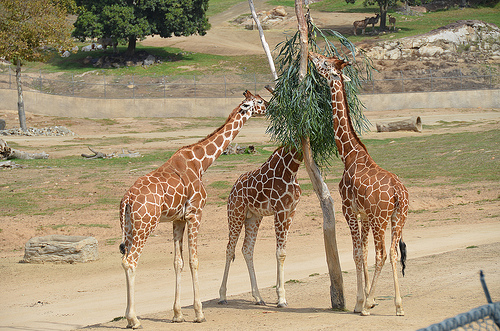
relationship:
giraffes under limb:
[116, 89, 276, 324] [264, 5, 373, 176]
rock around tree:
[8, 123, 74, 140] [1, 2, 80, 134]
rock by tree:
[8, 123, 74, 140] [1, 2, 80, 134]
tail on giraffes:
[119, 201, 129, 254] [116, 89, 276, 324]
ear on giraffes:
[332, 56, 342, 70] [308, 51, 411, 315]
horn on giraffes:
[242, 89, 252, 98] [116, 89, 276, 324]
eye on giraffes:
[256, 98, 262, 106] [116, 89, 276, 324]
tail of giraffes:
[119, 201, 129, 254] [116, 89, 276, 324]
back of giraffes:
[164, 143, 193, 172] [116, 89, 276, 324]